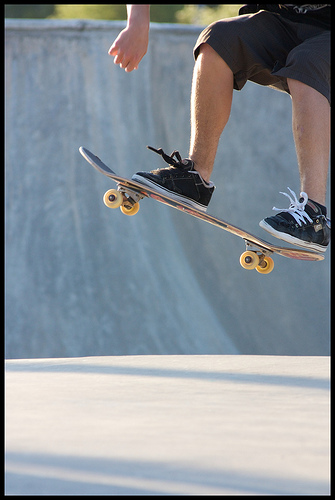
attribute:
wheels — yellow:
[98, 188, 124, 209]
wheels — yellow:
[121, 193, 142, 213]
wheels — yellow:
[236, 245, 259, 272]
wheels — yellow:
[258, 251, 278, 273]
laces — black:
[149, 144, 189, 171]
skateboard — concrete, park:
[77, 143, 322, 272]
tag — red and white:
[313, 223, 324, 235]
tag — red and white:
[300, 196, 319, 214]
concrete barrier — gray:
[24, 49, 333, 319]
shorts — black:
[188, 7, 334, 100]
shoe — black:
[119, 121, 226, 220]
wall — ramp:
[5, 18, 329, 357]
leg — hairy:
[289, 83, 333, 210]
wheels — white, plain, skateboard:
[102, 185, 273, 272]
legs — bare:
[187, 51, 328, 203]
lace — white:
[274, 184, 313, 224]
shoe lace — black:
[141, 144, 189, 173]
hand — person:
[105, 4, 157, 73]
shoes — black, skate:
[129, 144, 215, 214]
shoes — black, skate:
[258, 186, 333, 255]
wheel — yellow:
[252, 256, 274, 275]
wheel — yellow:
[237, 250, 259, 268]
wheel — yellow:
[118, 197, 140, 216]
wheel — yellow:
[102, 189, 125, 208]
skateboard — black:
[73, 135, 325, 285]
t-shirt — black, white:
[233, 1, 332, 34]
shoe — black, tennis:
[257, 179, 333, 257]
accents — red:
[146, 190, 235, 233]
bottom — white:
[258, 219, 327, 253]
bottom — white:
[130, 172, 207, 212]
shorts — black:
[194, 0, 332, 105]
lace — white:
[272, 181, 308, 224]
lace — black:
[140, 144, 194, 177]